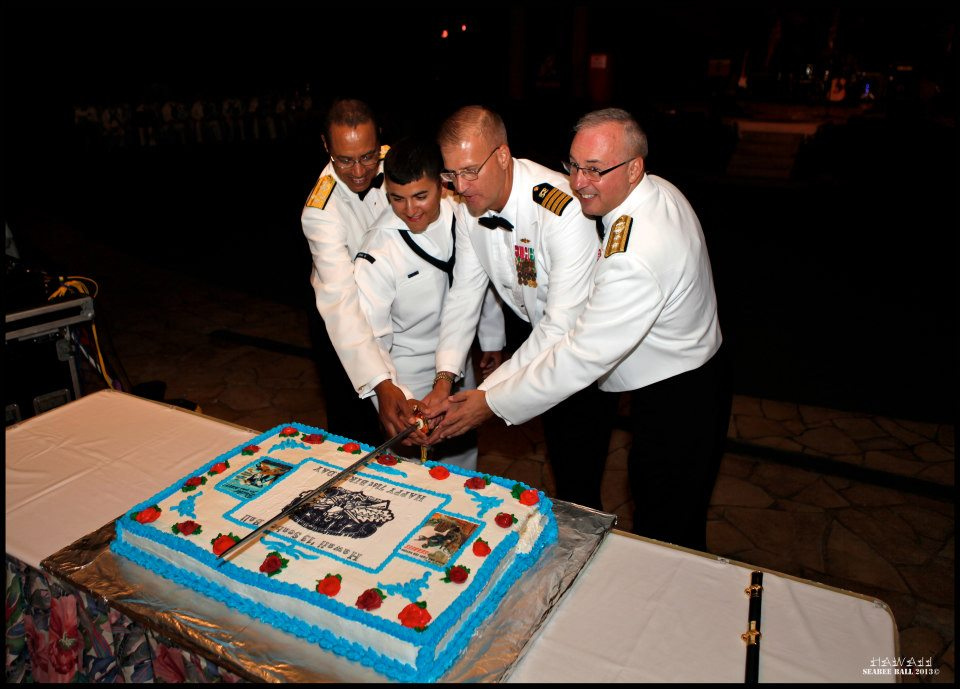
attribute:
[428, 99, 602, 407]
man — in uniform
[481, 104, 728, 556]
right man — wearing black pants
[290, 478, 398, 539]
black/white image — in center of cake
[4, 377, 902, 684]
white table — with cake on top of it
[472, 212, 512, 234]
bow tie — black, on man in uniform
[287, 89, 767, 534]
men — grouped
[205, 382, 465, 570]
knife — long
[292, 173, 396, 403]
shirt — white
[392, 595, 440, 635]
flower — red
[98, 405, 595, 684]
cake — blue, white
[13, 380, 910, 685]
covering — white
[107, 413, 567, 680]
cake — white, blue, red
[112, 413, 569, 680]
frosting — blue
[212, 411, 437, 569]
knife — long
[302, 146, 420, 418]
shirts — white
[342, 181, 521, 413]
shirts — white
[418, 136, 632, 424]
shirts — white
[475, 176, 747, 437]
shirts — white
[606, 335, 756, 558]
pants — black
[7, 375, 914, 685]
table — white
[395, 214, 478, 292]
tie — black